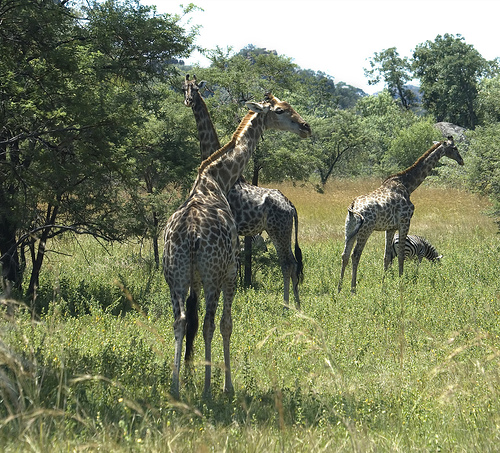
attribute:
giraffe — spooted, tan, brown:
[184, 82, 312, 312]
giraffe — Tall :
[177, 85, 288, 269]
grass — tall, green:
[5, 228, 498, 448]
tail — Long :
[182, 239, 203, 345]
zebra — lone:
[392, 236, 443, 268]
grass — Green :
[2, 171, 499, 451]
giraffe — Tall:
[142, 83, 496, 370]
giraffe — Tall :
[329, 126, 464, 308]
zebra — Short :
[390, 230, 465, 273]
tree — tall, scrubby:
[0, 0, 207, 321]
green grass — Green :
[366, 289, 443, 321]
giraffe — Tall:
[333, 125, 460, 273]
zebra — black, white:
[404, 231, 444, 264]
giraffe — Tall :
[334, 139, 475, 291]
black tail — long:
[180, 295, 202, 378]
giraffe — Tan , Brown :
[175, 71, 304, 316]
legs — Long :
[383, 228, 408, 281]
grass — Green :
[285, 293, 406, 412]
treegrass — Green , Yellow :
[16, 177, 490, 451]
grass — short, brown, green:
[13, 297, 171, 405]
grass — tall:
[303, 301, 484, 436]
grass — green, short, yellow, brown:
[320, 296, 490, 446]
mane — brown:
[396, 143, 450, 183]